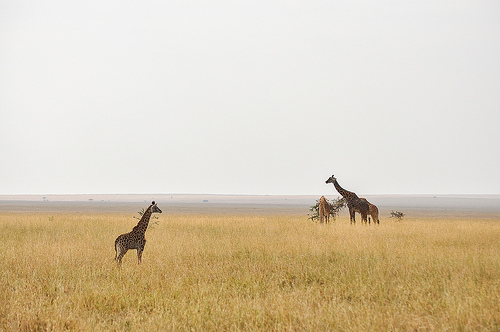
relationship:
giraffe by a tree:
[322, 172, 371, 224] [310, 191, 345, 224]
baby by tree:
[110, 200, 163, 269] [310, 191, 345, 224]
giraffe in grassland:
[322, 172, 371, 224] [1, 195, 499, 331]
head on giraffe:
[324, 173, 338, 184] [322, 172, 371, 224]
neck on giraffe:
[331, 180, 348, 199] [322, 172, 371, 224]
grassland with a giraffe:
[1, 195, 499, 331] [322, 172, 371, 224]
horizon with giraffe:
[0, 191, 499, 211] [322, 172, 371, 224]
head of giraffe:
[324, 173, 338, 184] [322, 172, 371, 224]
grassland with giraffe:
[1, 195, 499, 331] [322, 172, 371, 224]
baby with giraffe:
[110, 200, 163, 269] [322, 172, 371, 224]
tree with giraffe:
[310, 191, 345, 224] [322, 172, 371, 224]